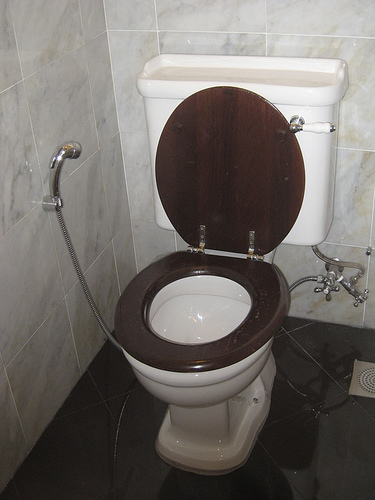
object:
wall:
[0, 0, 374, 493]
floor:
[0, 315, 374, 498]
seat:
[114, 251, 291, 373]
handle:
[288, 114, 337, 136]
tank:
[135, 53, 349, 246]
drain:
[348, 358, 374, 398]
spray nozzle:
[49, 139, 82, 195]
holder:
[42, 192, 64, 210]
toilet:
[121, 334, 277, 476]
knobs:
[313, 256, 370, 307]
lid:
[154, 85, 305, 255]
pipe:
[289, 245, 365, 291]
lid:
[136, 52, 349, 107]